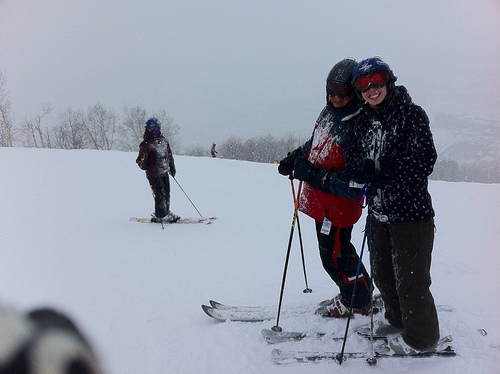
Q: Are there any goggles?
A: Yes, there are goggles.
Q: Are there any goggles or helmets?
A: Yes, there are goggles.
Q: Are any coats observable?
A: Yes, there is a coat.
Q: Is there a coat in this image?
A: Yes, there is a coat.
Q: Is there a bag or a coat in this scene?
A: Yes, there is a coat.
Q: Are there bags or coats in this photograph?
A: Yes, there is a coat.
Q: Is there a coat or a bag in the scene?
A: Yes, there is a coat.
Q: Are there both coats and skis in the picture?
A: Yes, there are both a coat and skis.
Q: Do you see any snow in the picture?
A: Yes, there is snow.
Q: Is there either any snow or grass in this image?
A: Yes, there is snow.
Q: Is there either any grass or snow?
A: Yes, there is snow.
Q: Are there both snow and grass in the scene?
A: No, there is snow but no grass.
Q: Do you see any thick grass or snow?
A: Yes, there is thick snow.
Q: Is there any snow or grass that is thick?
A: Yes, the snow is thick.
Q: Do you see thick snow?
A: Yes, there is thick snow.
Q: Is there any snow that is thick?
A: Yes, there is snow that is thick.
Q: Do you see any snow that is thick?
A: Yes, there is snow that is thick.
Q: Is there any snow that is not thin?
A: Yes, there is thick snow.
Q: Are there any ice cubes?
A: No, there are no ice cubes.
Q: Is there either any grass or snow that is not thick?
A: No, there is snow but it is thick.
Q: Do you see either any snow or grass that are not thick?
A: No, there is snow but it is thick.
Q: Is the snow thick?
A: Yes, the snow is thick.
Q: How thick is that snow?
A: The snow is thick.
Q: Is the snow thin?
A: No, the snow is thick.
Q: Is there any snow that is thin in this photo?
A: No, there is snow but it is thick.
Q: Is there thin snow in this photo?
A: No, there is snow but it is thick.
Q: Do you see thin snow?
A: No, there is snow but it is thick.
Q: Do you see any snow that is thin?
A: No, there is snow but it is thick.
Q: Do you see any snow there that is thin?
A: No, there is snow but it is thick.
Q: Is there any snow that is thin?
A: No, there is snow but it is thick.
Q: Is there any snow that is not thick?
A: No, there is snow but it is thick.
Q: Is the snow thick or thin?
A: The snow is thick.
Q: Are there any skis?
A: Yes, there are skis.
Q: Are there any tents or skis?
A: Yes, there are skis.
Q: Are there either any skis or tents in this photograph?
A: Yes, there are skis.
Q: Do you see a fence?
A: No, there are no fences.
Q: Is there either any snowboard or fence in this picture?
A: No, there are no fences or snowboards.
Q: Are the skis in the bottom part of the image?
A: Yes, the skis are in the bottom of the image.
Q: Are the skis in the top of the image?
A: No, the skis are in the bottom of the image.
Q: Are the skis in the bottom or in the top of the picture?
A: The skis are in the bottom of the image.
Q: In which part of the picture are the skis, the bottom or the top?
A: The skis are in the bottom of the image.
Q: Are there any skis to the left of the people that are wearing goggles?
A: Yes, there are skis to the left of the people.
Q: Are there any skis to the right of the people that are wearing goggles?
A: No, the skis are to the left of the people.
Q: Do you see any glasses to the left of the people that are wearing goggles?
A: No, there are skis to the left of the people.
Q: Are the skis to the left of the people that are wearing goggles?
A: Yes, the skis are to the left of the people.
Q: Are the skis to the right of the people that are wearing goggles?
A: No, the skis are to the left of the people.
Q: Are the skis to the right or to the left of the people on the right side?
A: The skis are to the left of the people.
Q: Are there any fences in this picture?
A: No, there are no fences.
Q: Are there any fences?
A: No, there are no fences.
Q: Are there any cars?
A: No, there are no cars.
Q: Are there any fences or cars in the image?
A: No, there are no cars or fences.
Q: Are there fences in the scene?
A: No, there are no fences.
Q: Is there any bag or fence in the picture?
A: No, there are no fences or bags.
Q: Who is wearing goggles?
A: The people are wearing goggles.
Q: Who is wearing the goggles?
A: The people are wearing goggles.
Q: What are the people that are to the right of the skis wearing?
A: The people are wearing goggles.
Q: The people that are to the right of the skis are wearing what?
A: The people are wearing goggles.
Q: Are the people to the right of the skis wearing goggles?
A: Yes, the people are wearing goggles.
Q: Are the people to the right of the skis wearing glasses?
A: No, the people are wearing goggles.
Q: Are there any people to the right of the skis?
A: Yes, there are people to the right of the skis.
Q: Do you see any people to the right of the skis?
A: Yes, there are people to the right of the skis.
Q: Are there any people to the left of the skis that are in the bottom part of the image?
A: No, the people are to the right of the skis.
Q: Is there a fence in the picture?
A: No, there are no fences.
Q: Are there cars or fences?
A: No, there are no fences or cars.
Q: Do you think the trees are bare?
A: Yes, the trees are bare.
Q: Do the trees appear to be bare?
A: Yes, the trees are bare.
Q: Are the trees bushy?
A: No, the trees are bare.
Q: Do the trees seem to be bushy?
A: No, the trees are bare.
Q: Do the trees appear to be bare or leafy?
A: The trees are bare.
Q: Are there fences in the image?
A: No, there are no fences.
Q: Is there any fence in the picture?
A: No, there are no fences.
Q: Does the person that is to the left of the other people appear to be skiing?
A: Yes, the person is skiing.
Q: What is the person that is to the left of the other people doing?
A: The person is skiing.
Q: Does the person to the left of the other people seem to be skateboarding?
A: No, the person is skiing.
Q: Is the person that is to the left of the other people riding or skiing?
A: The person is skiing.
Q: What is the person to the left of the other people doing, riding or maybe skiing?
A: The person is skiing.